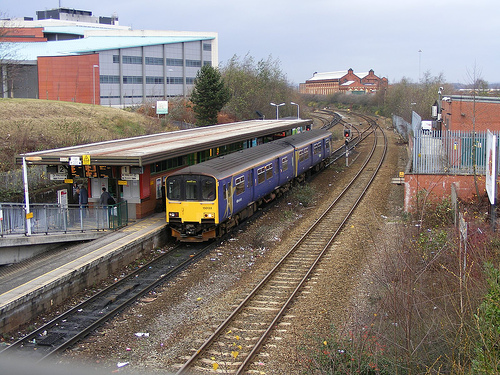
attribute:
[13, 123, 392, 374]
tracks — blue, brown, black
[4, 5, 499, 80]
sky — open, blue, clear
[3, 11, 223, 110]
building — wide, white, orange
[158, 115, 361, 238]
train — short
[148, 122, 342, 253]
train — yellow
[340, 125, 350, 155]
lights — red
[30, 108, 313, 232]
train station — long, narrow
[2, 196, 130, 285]
access — sloped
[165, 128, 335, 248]
train — stopped, wide, short, yellow, blue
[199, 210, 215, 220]
light — on